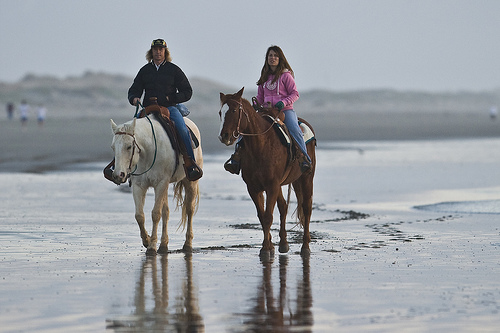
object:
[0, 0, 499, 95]
sky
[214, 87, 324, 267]
horse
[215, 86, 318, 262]
hosre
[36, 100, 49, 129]
people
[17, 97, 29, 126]
people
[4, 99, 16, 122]
people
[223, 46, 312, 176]
girl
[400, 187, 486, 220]
water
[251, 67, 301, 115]
jacket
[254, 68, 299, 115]
pink top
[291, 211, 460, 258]
signs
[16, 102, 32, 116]
blue shirt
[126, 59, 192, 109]
black jacket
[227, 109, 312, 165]
blue pants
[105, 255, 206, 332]
reflection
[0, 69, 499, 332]
beach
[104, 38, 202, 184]
man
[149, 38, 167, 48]
ballcap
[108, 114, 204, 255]
horse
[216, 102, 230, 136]
white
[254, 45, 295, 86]
hair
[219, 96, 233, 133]
forehead